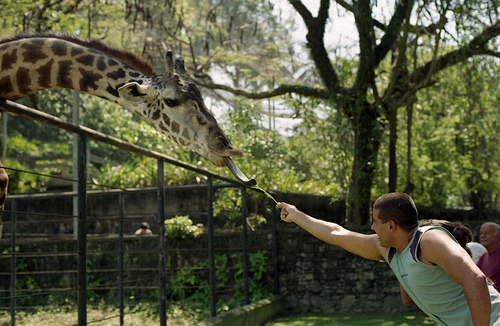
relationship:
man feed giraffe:
[270, 188, 495, 322] [15, 12, 253, 189]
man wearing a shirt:
[470, 214, 495, 308] [477, 250, 498, 282]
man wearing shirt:
[270, 188, 495, 322] [379, 221, 498, 318]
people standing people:
[276, 193, 488, 323] [452, 207, 495, 277]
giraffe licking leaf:
[6, 28, 243, 176] [246, 180, 283, 205]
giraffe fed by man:
[17, 19, 288, 201] [270, 188, 495, 322]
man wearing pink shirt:
[266, 170, 487, 324] [483, 252, 499, 278]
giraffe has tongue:
[26, 53, 251, 155] [212, 151, 324, 195]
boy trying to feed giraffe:
[275, 190, 497, 325] [0, 28, 256, 186]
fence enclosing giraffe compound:
[2, 96, 284, 324] [1, 28, 289, 323]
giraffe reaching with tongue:
[4, 21, 274, 209] [215, 159, 262, 193]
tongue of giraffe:
[219, 155, 256, 185] [1, 31, 256, 230]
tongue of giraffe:
[221, 155, 258, 187] [0, 28, 256, 186]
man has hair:
[270, 188, 495, 322] [373, 192, 417, 232]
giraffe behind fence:
[0, 28, 256, 186] [2, 96, 284, 324]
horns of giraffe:
[159, 44, 189, 74] [43, 45, 247, 211]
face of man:
[363, 212, 393, 248] [270, 188, 495, 322]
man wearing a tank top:
[270, 188, 495, 322] [381, 224, 498, 322]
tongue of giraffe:
[223, 154, 256, 184] [0, 33, 242, 165]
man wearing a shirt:
[266, 170, 487, 324] [372, 224, 492, 322]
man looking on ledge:
[133, 222, 155, 239] [1, 193, 432, 310]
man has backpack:
[270, 188, 495, 322] [421, 205, 469, 231]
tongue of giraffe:
[224, 160, 259, 187] [0, 28, 256, 186]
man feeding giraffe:
[322, 172, 478, 296] [0, 28, 256, 186]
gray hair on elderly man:
[484, 219, 499, 230] [475, 216, 499, 274]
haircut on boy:
[376, 195, 415, 224] [275, 190, 497, 325]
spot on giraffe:
[106, 67, 129, 79] [0, 28, 256, 186]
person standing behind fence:
[132, 220, 156, 246] [26, 108, 282, 320]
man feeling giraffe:
[270, 188, 495, 322] [0, 28, 256, 186]